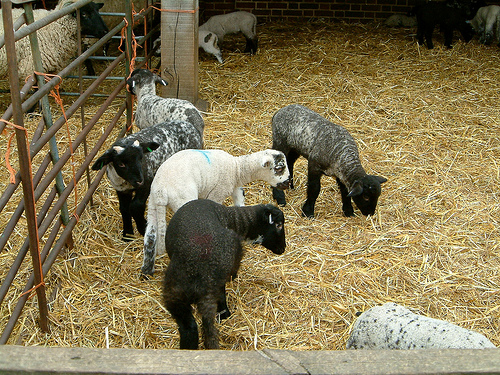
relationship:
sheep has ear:
[92, 120, 199, 243] [141, 140, 157, 154]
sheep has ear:
[92, 120, 199, 243] [90, 150, 111, 172]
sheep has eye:
[158, 197, 288, 347] [274, 222, 283, 232]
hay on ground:
[1, 21, 496, 349] [3, 27, 499, 351]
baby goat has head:
[269, 104, 387, 219] [344, 175, 388, 218]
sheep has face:
[0, 1, 110, 92] [78, 2, 110, 40]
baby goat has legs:
[269, 104, 387, 219] [272, 145, 352, 218]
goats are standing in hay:
[91, 1, 497, 349] [1, 21, 496, 349]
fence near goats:
[2, 1, 159, 344] [91, 1, 497, 349]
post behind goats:
[159, 0, 201, 108] [91, 1, 497, 349]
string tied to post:
[114, 6, 198, 133] [159, 0, 201, 108]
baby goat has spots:
[342, 300, 499, 349] [348, 300, 495, 349]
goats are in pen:
[91, 1, 497, 349] [3, 25, 499, 343]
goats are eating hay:
[91, 1, 497, 349] [1, 21, 496, 349]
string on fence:
[114, 6, 198, 133] [2, 1, 159, 344]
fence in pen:
[2, 1, 159, 344] [3, 25, 499, 343]